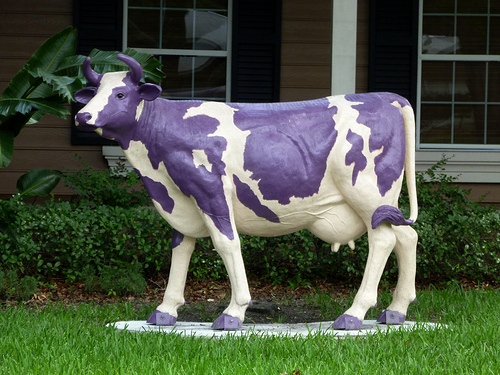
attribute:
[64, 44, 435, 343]
statue — cow, black, white, plaster-based, purple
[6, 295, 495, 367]
grass — green, long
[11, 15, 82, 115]
bushes — green, large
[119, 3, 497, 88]
window — white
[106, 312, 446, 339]
platform — concrete, white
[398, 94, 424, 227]
tail — black, white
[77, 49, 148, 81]
horns — purple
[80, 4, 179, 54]
siding — brown